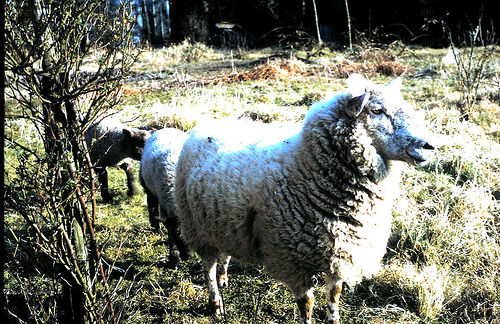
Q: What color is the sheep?
A: Dirty white.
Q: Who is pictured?
A: No one.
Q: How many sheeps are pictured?
A: Two.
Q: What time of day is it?
A: Day time.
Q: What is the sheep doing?
A: Standing.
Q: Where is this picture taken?
A: In a pasture.